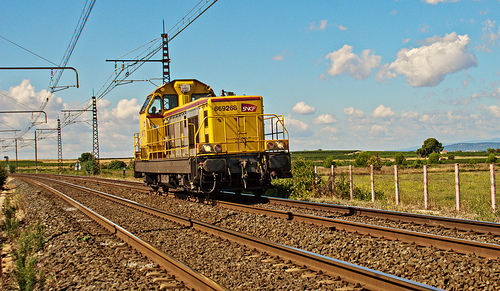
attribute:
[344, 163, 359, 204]
fence post — wooden fence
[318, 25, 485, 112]
cumulus clouds — several 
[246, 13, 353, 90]
blue sky — blue 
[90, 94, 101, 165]
post — wooden fence 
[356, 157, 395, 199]
post — wooden fence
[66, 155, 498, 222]
fence — wooden fence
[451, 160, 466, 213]
post — wooden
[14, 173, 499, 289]
rock — brown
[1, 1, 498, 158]
sky — blue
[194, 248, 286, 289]
rock — brown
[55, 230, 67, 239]
rock — brown 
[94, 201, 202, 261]
brown rocks — brown 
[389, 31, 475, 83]
clouds — cumulus 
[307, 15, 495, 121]
sky — blue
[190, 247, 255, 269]
rock — brown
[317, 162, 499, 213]
meadow — Open 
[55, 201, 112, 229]
rock — brown 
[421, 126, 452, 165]
tree — Big , green 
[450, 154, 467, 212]
post — wooden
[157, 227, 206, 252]
rocks — brown 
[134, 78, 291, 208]
train — yellow